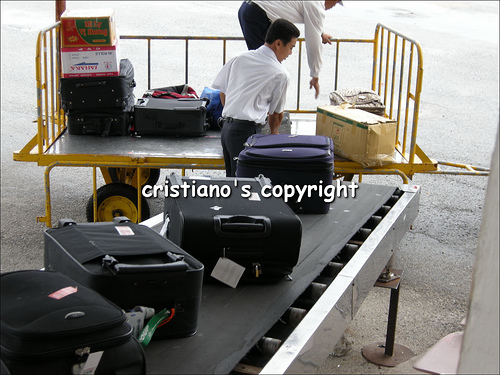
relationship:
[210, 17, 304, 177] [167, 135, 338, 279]
man have luggage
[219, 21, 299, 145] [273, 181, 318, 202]
man has handle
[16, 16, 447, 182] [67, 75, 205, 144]
cart has luggage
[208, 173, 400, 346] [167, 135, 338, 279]
conveyor belt has luggage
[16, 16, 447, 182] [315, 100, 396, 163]
car has box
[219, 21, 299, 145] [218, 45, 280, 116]
man wearing shirt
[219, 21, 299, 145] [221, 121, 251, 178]
man wearing pants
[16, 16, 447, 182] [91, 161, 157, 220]
cart has wheels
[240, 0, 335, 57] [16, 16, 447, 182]
man on cart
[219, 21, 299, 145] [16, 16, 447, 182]
man beside cart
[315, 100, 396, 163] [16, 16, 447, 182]
box on top of cart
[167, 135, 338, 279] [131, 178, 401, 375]
luggage on top of conveyor belt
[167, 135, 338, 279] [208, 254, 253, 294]
luggage has name tag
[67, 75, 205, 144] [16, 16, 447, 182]
luggage on top of cart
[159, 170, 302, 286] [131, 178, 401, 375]
suitcase on top of conveyor belt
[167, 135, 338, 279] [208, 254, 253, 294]
luggage has tags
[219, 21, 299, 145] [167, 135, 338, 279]
man lifting luggage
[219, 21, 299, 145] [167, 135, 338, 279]
man moving luggage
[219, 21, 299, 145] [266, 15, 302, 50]
man has hair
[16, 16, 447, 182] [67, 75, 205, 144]
cart transports luggage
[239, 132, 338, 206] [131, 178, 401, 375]
suitcase on top of conveyor belt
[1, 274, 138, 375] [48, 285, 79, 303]
luggage has tag